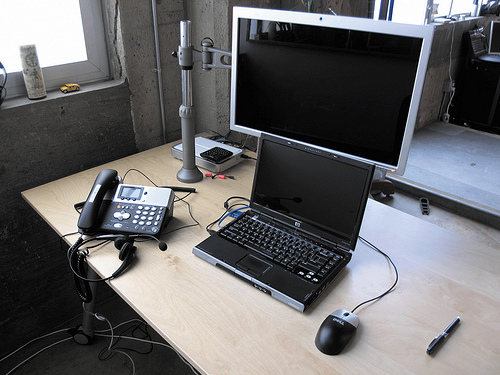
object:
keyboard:
[212, 208, 349, 285]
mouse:
[313, 307, 361, 358]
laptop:
[189, 132, 376, 313]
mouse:
[310, 234, 398, 356]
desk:
[18, 129, 495, 372]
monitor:
[228, 6, 433, 176]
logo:
[292, 219, 300, 230]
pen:
[423, 317, 462, 356]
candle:
[16, 43, 47, 101]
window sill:
[0, 78, 140, 361]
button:
[148, 205, 157, 211]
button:
[112, 222, 123, 228]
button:
[135, 205, 142, 210]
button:
[144, 220, 154, 226]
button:
[146, 215, 153, 220]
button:
[131, 213, 140, 221]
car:
[58, 80, 83, 94]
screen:
[250, 137, 370, 243]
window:
[1, 0, 113, 103]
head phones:
[66, 233, 138, 284]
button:
[139, 214, 146, 222]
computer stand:
[173, 19, 231, 184]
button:
[132, 214, 141, 219]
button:
[120, 211, 131, 219]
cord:
[349, 234, 398, 313]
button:
[130, 219, 138, 224]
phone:
[75, 167, 175, 236]